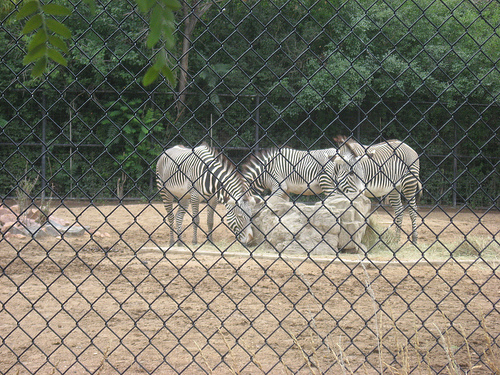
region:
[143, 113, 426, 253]
Zebras in the photo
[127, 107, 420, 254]
Three zebras in the picture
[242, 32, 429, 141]
Trees at the back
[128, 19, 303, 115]
Trees in the photo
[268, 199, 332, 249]
Rocks in the photo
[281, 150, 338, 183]
Black and white stripes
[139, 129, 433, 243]
Zebras near a watering point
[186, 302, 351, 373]
Bare ground in the photo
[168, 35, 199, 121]
A tree trunk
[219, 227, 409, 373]
Wire mesh fence in the picture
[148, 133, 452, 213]
three zebras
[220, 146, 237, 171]
the zebras hair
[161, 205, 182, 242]
zebras leg is black and white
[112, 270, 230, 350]
the dirt is on the ground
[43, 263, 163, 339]
the dirt is brown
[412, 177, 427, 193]
the zebras tail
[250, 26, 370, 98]
the bush is green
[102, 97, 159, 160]
the leaves are green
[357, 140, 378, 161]
the zebra ear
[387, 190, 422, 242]
the zebras leg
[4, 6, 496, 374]
Grey chain link fence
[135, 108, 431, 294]
Group of three zebras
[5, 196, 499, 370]
Brown dirt ground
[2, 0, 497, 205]
trees in the distance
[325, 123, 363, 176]
Zebra with black mane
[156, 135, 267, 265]
Black stripes on zebra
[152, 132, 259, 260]
zebra looking for food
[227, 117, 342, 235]
Zebra eating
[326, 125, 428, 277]
Zebra turning his head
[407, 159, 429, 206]
White tail on zebra with black stripes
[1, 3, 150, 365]
the chain lik fence to the kennle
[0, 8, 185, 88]
the leave hanging in front of the fence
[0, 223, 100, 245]
the rocks in the zebra cage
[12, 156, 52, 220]
the weeds growing by the rocks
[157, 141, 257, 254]
the zebra grazing off the ground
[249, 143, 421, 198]
the zebras behind the rocks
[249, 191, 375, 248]
the boulder in the center of the kennel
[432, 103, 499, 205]
the fence behind the zebras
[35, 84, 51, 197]
the black pole for the fence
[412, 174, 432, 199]
the tail of the zebra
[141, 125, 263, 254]
a zebra eating dry grass.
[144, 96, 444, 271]
a herd of zebra in a field.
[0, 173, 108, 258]
a zebra laying on the ground.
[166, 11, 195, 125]
a tall brown tree branch.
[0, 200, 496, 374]
a field of brown dry grass.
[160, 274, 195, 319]
a section of chain link fence.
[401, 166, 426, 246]
a zebra hind leg.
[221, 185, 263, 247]
a head on a zebra.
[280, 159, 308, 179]
a section of stripes on a zebra.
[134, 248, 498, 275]
a section of dry grass.